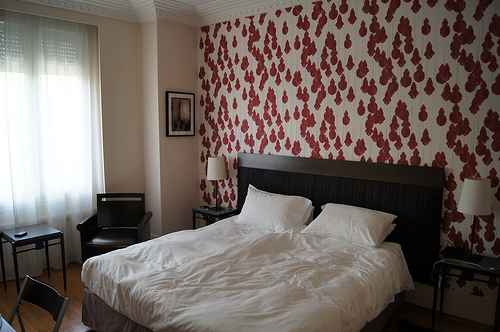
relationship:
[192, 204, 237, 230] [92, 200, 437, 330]
night stand next to bed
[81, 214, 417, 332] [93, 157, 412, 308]
spread on top of bed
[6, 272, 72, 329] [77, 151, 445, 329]
desk chair at end of bed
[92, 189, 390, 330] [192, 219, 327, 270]
bed has spread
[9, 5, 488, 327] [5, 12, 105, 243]
room has curtains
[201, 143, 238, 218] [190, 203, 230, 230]
lamp on nightstand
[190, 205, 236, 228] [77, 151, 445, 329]
night stand left of bed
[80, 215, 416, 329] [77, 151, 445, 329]
sheets on bed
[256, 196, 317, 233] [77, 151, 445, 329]
pillow on bed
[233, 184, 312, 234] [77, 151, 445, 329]
pillow on bed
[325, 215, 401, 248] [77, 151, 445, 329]
pillow on bed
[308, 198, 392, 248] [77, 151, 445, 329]
pillow on bed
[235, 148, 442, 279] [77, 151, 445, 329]
headboard on bed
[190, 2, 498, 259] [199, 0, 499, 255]
wallpaper on wall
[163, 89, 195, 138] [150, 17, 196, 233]
art on wall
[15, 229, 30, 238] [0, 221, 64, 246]
remote control on small table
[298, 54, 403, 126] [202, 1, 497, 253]
red dots on wall paper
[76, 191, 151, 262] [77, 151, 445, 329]
chair next to bed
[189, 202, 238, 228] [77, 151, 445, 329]
nightstand next to bed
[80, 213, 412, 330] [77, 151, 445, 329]
white spread on top of bed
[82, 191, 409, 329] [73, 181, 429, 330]
spread on top of bed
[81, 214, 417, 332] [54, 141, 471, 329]
spread on top of bed